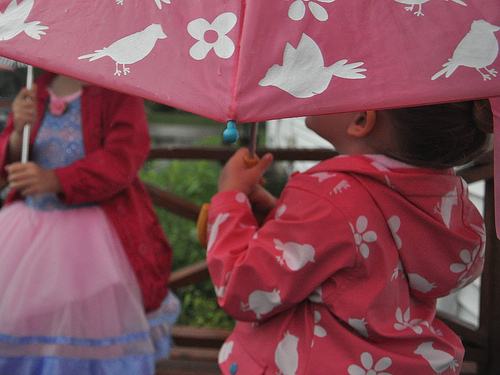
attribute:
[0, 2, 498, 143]
umbrella — matching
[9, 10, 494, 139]
umbrella — pink, tip, pole, metal, wooden, bird, holding, red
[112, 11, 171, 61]
bird — white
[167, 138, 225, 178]
railing — wooden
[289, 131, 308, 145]
building — white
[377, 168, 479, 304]
hood — hanging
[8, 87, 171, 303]
baby — under, wearing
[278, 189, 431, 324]
jacket — rain, matching, red, white, hooded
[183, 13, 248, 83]
pattern — flower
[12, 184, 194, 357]
costume — princess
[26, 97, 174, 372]
she — wearing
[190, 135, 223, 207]
fence — wooden, wood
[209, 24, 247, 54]
flower — white, pink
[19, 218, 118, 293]
skirt — pink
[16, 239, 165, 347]
dress — pink, line, sparkle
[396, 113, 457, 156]
hair — brown